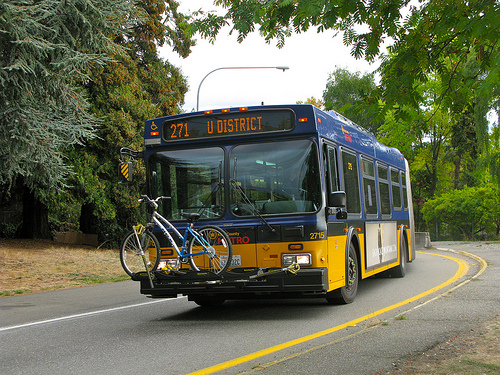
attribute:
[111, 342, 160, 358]
pavement — gray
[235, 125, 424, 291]
bus — yellow, gold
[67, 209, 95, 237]
tree — green, pine needles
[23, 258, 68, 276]
dirt — brown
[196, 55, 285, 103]
street light — off, on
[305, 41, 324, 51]
sky — white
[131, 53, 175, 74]
leaves — green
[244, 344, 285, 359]
lines — yellow, white, curved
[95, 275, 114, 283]
grass — dry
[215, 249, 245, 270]
license plate — white